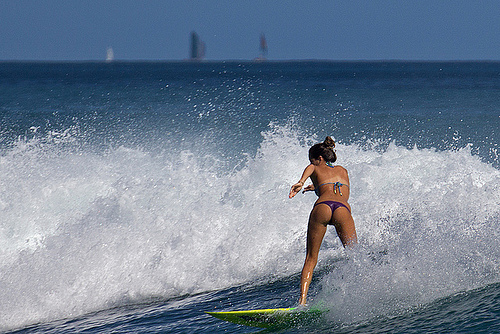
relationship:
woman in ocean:
[288, 134, 368, 309] [0, 54, 500, 333]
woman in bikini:
[288, 134, 368, 309] [311, 162, 350, 227]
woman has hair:
[288, 134, 368, 309] [309, 143, 335, 157]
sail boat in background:
[107, 43, 115, 64] [4, 44, 499, 65]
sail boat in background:
[187, 28, 209, 63] [4, 44, 499, 65]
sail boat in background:
[260, 32, 273, 59] [4, 44, 499, 65]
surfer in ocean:
[288, 134, 368, 309] [0, 54, 500, 333]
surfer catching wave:
[288, 134, 368, 309] [9, 132, 493, 304]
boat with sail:
[187, 28, 209, 63] [192, 32, 198, 52]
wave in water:
[9, 132, 493, 304] [0, 54, 500, 333]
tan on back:
[321, 166, 331, 175] [316, 165, 351, 203]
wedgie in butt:
[331, 205, 337, 227] [313, 200, 353, 228]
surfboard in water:
[195, 299, 347, 326] [0, 54, 500, 333]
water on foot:
[0, 54, 500, 333] [296, 302, 308, 305]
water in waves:
[0, 54, 500, 333] [9, 132, 493, 304]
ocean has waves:
[0, 54, 500, 333] [9, 132, 493, 304]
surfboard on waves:
[195, 299, 347, 326] [9, 132, 493, 304]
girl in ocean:
[288, 134, 368, 309] [0, 54, 500, 333]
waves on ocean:
[9, 132, 493, 304] [0, 54, 500, 333]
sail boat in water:
[250, 30, 271, 62] [0, 54, 500, 333]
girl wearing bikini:
[288, 134, 368, 309] [311, 162, 350, 227]